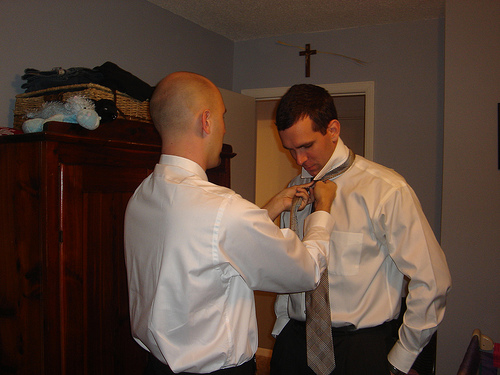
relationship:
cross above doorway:
[299, 43, 317, 77] [215, 55, 407, 235]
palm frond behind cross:
[277, 37, 364, 66] [298, 40, 318, 75]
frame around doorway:
[243, 78, 373, 160] [255, 94, 366, 206]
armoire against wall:
[5, 113, 234, 370] [3, 2, 230, 124]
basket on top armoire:
[13, 81, 153, 125] [5, 113, 234, 370]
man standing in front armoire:
[115, 73, 338, 372] [5, 113, 234, 370]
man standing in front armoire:
[271, 82, 454, 372] [5, 113, 234, 370]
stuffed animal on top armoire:
[21, 94, 101, 132] [5, 113, 234, 370]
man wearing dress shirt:
[115, 73, 338, 372] [120, 152, 331, 368]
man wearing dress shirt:
[271, 82, 454, 372] [267, 137, 449, 371]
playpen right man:
[457, 328, 498, 370] [271, 82, 454, 372]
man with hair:
[271, 82, 454, 372] [272, 81, 340, 132]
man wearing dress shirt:
[115, 73, 338, 372] [120, 152, 331, 373]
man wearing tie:
[271, 82, 454, 372] [289, 147, 355, 367]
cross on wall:
[299, 43, 317, 77] [233, 12, 494, 371]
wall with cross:
[233, 12, 494, 371] [298, 40, 317, 78]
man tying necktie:
[115, 73, 338, 372] [283, 147, 359, 370]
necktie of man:
[283, 147, 359, 370] [271, 82, 454, 372]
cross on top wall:
[297, 41, 319, 79] [233, 12, 494, 371]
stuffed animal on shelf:
[22, 94, 102, 134] [7, 115, 234, 371]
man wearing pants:
[271, 82, 454, 372] [266, 319, 404, 371]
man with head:
[115, 73, 338, 372] [147, 69, 227, 169]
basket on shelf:
[13, 83, 153, 123] [3, 80, 159, 131]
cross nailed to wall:
[299, 43, 317, 77] [233, 12, 494, 371]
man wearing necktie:
[271, 82, 454, 372] [293, 148, 358, 373]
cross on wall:
[299, 43, 317, 77] [236, 14, 442, 236]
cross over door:
[299, 43, 317, 77] [210, 83, 364, 208]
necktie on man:
[289, 147, 354, 375] [271, 82, 454, 372]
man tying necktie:
[115, 73, 338, 372] [289, 147, 354, 375]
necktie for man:
[289, 147, 354, 375] [271, 82, 454, 372]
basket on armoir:
[13, 83, 153, 123] [4, 115, 237, 370]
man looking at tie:
[271, 82, 454, 372] [289, 147, 355, 367]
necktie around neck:
[289, 147, 354, 375] [297, 141, 354, 182]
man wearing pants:
[271, 82, 454, 372] [271, 307, 430, 372]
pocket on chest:
[322, 223, 367, 277] [287, 182, 379, 321]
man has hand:
[271, 82, 454, 372] [379, 360, 407, 372]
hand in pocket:
[379, 360, 407, 372] [370, 350, 405, 370]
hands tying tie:
[268, 180, 341, 211] [299, 146, 355, 370]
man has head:
[115, 73, 338, 372] [147, 69, 227, 169]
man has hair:
[271, 82, 454, 372] [272, 81, 340, 132]